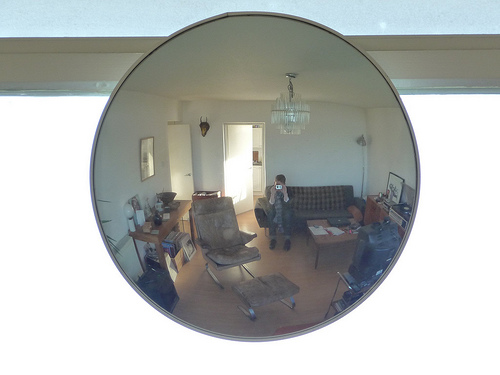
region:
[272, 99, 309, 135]
Crystals on a chandelier hanging from the ceiling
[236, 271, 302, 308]
Top of a leather ottoman in front of a chair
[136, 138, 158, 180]
Framed picture hanging on the wall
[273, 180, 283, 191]
A camera held by a person taking a photo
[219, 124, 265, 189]
Doorway reflected in the mirror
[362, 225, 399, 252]
Wheeled suitcase on the floor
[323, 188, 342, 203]
Plaid blanket on the back of a couch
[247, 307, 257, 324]
Shiny curved metal legs on an ottoman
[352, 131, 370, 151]
Top of a tall lamp in the corner of the room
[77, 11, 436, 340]
Round mirror showing the reflection of a room it faces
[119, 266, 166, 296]
edge of a mirror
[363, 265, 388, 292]
part of a mirror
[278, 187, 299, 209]
part of a sofa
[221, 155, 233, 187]
edge of a door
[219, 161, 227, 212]
side of a door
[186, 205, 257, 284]
part of a chair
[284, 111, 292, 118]
part of a light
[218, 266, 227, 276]
edge of a seat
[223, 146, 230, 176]
edge of a door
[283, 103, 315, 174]
part of a mirror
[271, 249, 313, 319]
part of a mirror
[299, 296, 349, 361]
edge of a mirror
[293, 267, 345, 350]
part of a mirror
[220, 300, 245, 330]
part of a floor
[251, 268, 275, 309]
part of a table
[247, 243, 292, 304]
part of a mirror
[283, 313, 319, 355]
edge of a mirror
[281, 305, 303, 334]
part of a floor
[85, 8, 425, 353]
a round rearview mirror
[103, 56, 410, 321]
a living room reflected on mirror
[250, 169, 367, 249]
person sits on a couch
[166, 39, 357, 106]
ceiling of room is white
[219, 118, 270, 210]
door of a room is white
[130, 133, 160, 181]
a picture over a table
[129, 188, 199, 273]
a table against the wall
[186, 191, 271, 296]
a brown rocking chair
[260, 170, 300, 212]
person is taking a picture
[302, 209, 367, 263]
a center table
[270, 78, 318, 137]
a large white chandelier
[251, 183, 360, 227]
a green sofa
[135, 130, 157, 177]
a picture frame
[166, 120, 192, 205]
a large white door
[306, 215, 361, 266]
a large brown coffee table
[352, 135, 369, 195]
a tall floor lamp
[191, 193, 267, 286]
a large brown chair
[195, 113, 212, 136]
a small brown wall statue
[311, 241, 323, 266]
a small table leg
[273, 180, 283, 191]
a silver camera